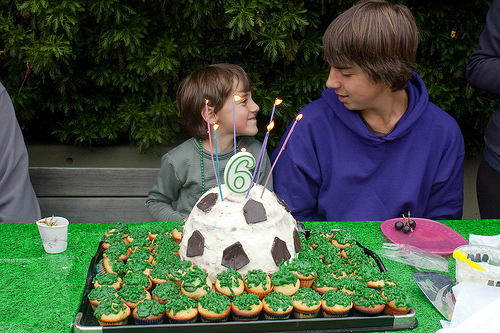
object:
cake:
[179, 183, 300, 272]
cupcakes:
[90, 299, 132, 315]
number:
[223, 151, 255, 193]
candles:
[192, 187, 220, 211]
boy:
[144, 61, 273, 222]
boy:
[272, 1, 464, 221]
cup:
[34, 215, 69, 252]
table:
[1, 220, 498, 332]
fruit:
[395, 221, 404, 230]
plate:
[381, 216, 468, 255]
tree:
[1, 0, 500, 150]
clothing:
[273, 70, 465, 219]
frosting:
[182, 184, 300, 273]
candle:
[242, 198, 267, 224]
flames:
[212, 122, 222, 132]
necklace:
[199, 137, 207, 194]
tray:
[74, 226, 418, 331]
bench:
[28, 163, 158, 222]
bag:
[381, 239, 449, 275]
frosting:
[90, 220, 411, 315]